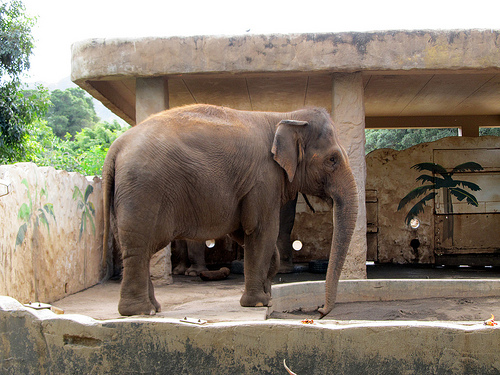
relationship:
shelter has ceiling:
[67, 30, 498, 275] [94, 71, 499, 126]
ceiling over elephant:
[94, 71, 499, 126] [100, 103, 357, 316]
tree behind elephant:
[0, 0, 35, 166] [100, 103, 357, 316]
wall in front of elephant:
[2, 295, 498, 374] [100, 103, 357, 316]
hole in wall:
[290, 238, 306, 251] [180, 132, 499, 276]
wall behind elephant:
[180, 132, 499, 276] [100, 103, 357, 316]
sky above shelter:
[2, 0, 497, 126] [67, 30, 498, 275]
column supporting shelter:
[327, 70, 370, 279] [67, 30, 498, 275]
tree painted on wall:
[398, 159, 484, 257] [202, 138, 498, 276]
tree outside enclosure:
[0, 0, 39, 161] [3, 143, 499, 373]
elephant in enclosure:
[100, 103, 357, 316] [3, 143, 499, 373]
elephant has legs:
[100, 103, 357, 316] [173, 230, 293, 279]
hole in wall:
[203, 236, 216, 248] [180, 132, 499, 276]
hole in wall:
[405, 213, 421, 230] [180, 132, 499, 276]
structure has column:
[70, 31, 499, 279] [327, 70, 370, 279]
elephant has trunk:
[100, 103, 357, 316] [318, 159, 360, 317]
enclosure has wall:
[3, 143, 499, 373] [180, 132, 499, 276]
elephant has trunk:
[100, 103, 357, 316] [312, 162, 362, 324]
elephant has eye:
[100, 103, 357, 316] [327, 152, 339, 166]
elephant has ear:
[100, 103, 357, 316] [267, 118, 308, 184]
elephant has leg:
[100, 103, 357, 316] [239, 189, 285, 306]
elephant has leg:
[100, 103, 357, 316] [113, 188, 162, 315]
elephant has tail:
[100, 103, 357, 316] [95, 143, 115, 266]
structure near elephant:
[70, 31, 499, 279] [100, 103, 357, 316]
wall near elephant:
[2, 156, 108, 306] [100, 103, 357, 316]